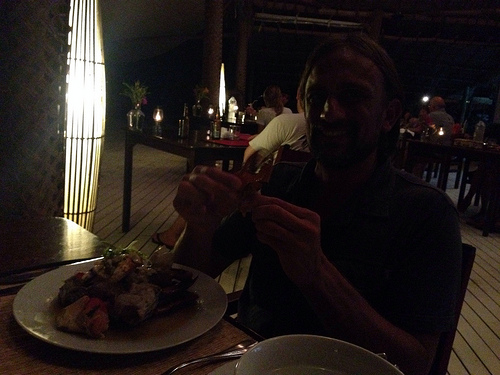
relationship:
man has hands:
[266, 42, 419, 302] [187, 165, 331, 273]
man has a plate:
[266, 42, 419, 302] [31, 260, 234, 346]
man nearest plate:
[266, 42, 419, 302] [31, 260, 234, 346]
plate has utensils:
[31, 260, 234, 346] [168, 344, 256, 370]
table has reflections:
[40, 208, 98, 267] [47, 220, 107, 255]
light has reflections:
[71, 11, 105, 226] [47, 220, 107, 255]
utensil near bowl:
[168, 344, 256, 370] [234, 336, 397, 370]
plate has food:
[31, 260, 234, 346] [67, 245, 214, 339]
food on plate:
[67, 245, 214, 339] [31, 260, 234, 346]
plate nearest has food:
[31, 260, 234, 346] [67, 245, 214, 339]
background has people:
[174, 15, 499, 108] [416, 92, 494, 130]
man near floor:
[266, 42, 419, 302] [91, 140, 178, 227]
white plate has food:
[35, 334, 226, 357] [67, 245, 214, 339]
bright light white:
[56, 41, 118, 139] [35, 334, 226, 357]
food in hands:
[67, 245, 214, 339] [187, 165, 331, 273]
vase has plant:
[123, 106, 152, 135] [122, 74, 143, 116]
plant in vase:
[122, 74, 143, 116] [123, 106, 152, 135]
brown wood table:
[4, 213, 100, 258] [40, 208, 98, 267]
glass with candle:
[215, 115, 233, 139] [215, 64, 225, 117]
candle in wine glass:
[215, 64, 225, 117] [149, 120, 165, 142]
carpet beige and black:
[431, 163, 469, 175] [446, 171, 488, 175]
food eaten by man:
[67, 245, 214, 339] [266, 42, 419, 302]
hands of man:
[187, 165, 331, 273] [266, 42, 419, 302]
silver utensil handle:
[168, 344, 256, 370] [230, 338, 258, 358]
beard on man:
[293, 132, 360, 151] [266, 42, 419, 302]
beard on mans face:
[293, 132, 360, 151] [299, 56, 375, 161]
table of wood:
[40, 208, 98, 267] [111, 128, 249, 222]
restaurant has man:
[6, 0, 493, 329] [266, 42, 419, 302]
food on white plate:
[67, 245, 214, 339] [31, 260, 234, 346]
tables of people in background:
[396, 124, 476, 198] [174, 15, 499, 108]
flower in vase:
[127, 82, 147, 113] [123, 106, 152, 135]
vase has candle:
[123, 106, 152, 135] [215, 64, 225, 117]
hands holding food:
[187, 165, 331, 273] [67, 245, 214, 339]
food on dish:
[67, 245, 214, 339] [31, 260, 234, 346]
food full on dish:
[67, 245, 214, 339] [31, 260, 234, 346]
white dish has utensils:
[35, 334, 226, 357] [168, 344, 256, 370]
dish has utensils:
[31, 260, 234, 346] [168, 344, 256, 370]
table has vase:
[40, 208, 98, 267] [123, 106, 152, 135]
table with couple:
[40, 208, 98, 267] [228, 95, 293, 119]